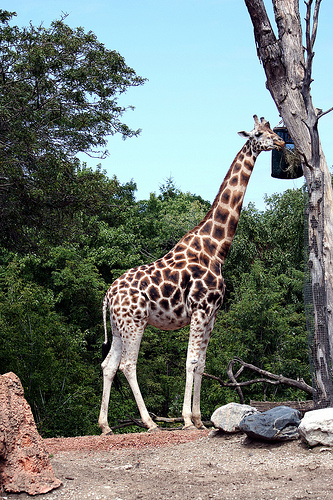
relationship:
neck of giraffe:
[198, 163, 265, 207] [68, 90, 293, 470]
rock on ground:
[188, 360, 317, 469] [64, 392, 261, 499]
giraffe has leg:
[68, 90, 293, 470] [154, 305, 233, 481]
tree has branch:
[260, 24, 312, 122] [221, 6, 280, 78]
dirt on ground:
[94, 407, 179, 457] [64, 392, 261, 499]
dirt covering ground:
[94, 407, 179, 457] [64, 392, 261, 499]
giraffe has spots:
[68, 90, 293, 470] [188, 202, 240, 276]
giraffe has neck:
[68, 90, 293, 470] [198, 163, 265, 207]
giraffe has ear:
[68, 90, 293, 470] [224, 119, 265, 141]